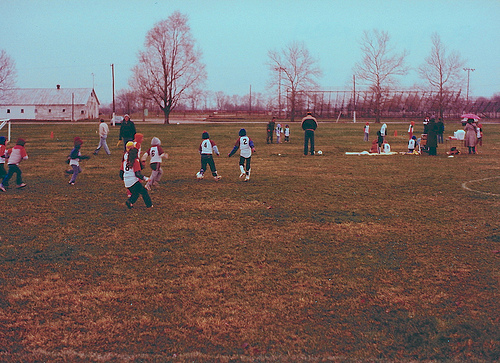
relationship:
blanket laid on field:
[342, 146, 418, 155] [161, 181, 498, 361]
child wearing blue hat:
[220, 115, 273, 196] [231, 115, 255, 138]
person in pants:
[62, 137, 89, 186] [71, 166, 79, 180]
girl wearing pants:
[108, 126, 158, 211] [124, 177, 154, 214]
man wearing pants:
[300, 106, 317, 156] [301, 131, 317, 154]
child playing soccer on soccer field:
[228, 127, 257, 181] [0, 123, 499, 362]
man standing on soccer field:
[300, 106, 317, 156] [2, 122, 490, 362]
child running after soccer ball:
[228, 127, 257, 181] [190, 168, 207, 178]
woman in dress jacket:
[461, 117, 478, 154] [465, 122, 477, 149]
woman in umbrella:
[461, 117, 478, 154] [459, 110, 481, 122]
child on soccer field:
[228, 127, 257, 181] [2, 122, 490, 362]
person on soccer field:
[362, 122, 369, 139] [2, 122, 490, 362]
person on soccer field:
[404, 136, 416, 151] [2, 122, 490, 362]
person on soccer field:
[147, 137, 169, 184] [2, 122, 490, 362]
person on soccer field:
[62, 137, 89, 182] [2, 122, 490, 362]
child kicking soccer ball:
[192, 128, 223, 180] [195, 171, 203, 179]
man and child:
[247, 117, 271, 151] [282, 120, 292, 146]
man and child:
[247, 117, 271, 151] [274, 119, 284, 145]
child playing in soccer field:
[0, 136, 30, 190] [0, 123, 499, 362]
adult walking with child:
[118, 114, 140, 151] [228, 127, 257, 181]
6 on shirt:
[149, 150, 155, 157] [145, 145, 164, 165]